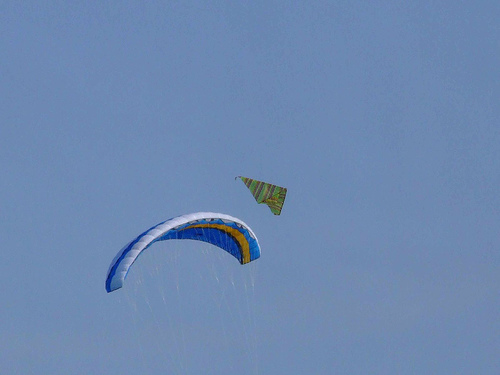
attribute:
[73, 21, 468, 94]
sky — blue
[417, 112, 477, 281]
clouds — white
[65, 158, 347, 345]
parasail — blue, yellow, black, white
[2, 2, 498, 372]
sky — blue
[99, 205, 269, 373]
windsail — arched